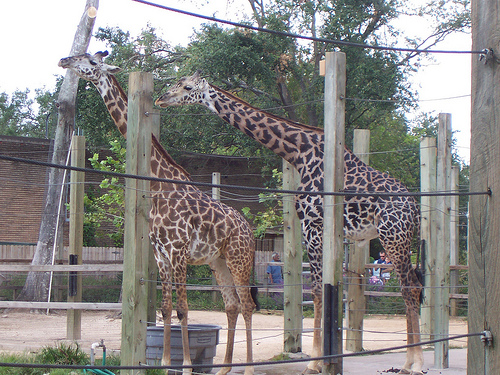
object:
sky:
[6, 3, 496, 49]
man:
[264, 252, 288, 290]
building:
[2, 139, 320, 307]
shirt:
[266, 261, 283, 284]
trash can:
[143, 323, 217, 373]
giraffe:
[56, 50, 258, 374]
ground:
[7, 304, 496, 365]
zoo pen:
[0, 0, 500, 368]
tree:
[92, 142, 122, 240]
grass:
[4, 349, 82, 374]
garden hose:
[84, 350, 116, 373]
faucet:
[93, 339, 107, 353]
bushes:
[13, 347, 65, 373]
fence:
[15, 162, 495, 374]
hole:
[143, 153, 145, 157]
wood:
[129, 121, 151, 219]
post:
[322, 51, 347, 366]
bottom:
[321, 283, 344, 371]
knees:
[161, 305, 172, 319]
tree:
[249, 1, 473, 248]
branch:
[355, 17, 469, 99]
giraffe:
[153, 67, 432, 373]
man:
[373, 250, 394, 284]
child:
[381, 257, 392, 275]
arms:
[382, 269, 397, 276]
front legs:
[157, 259, 175, 373]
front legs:
[299, 236, 326, 373]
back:
[179, 173, 253, 236]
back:
[320, 128, 410, 206]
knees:
[224, 303, 239, 316]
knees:
[399, 277, 420, 300]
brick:
[16, 202, 27, 211]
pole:
[121, 69, 153, 372]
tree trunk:
[23, 1, 96, 305]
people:
[380, 256, 390, 284]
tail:
[250, 230, 259, 308]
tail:
[414, 236, 426, 306]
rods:
[116, 0, 491, 59]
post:
[466, 0, 500, 369]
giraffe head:
[58, 50, 120, 81]